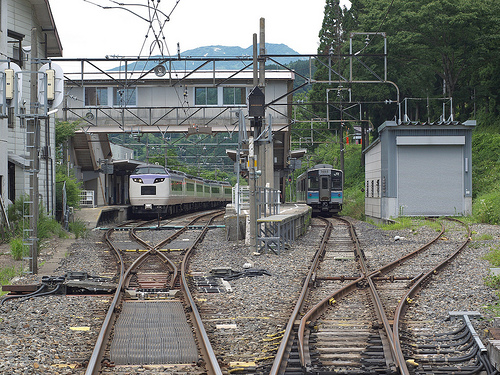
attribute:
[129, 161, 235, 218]
train — facing forward, tan, purple, white, blue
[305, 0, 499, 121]
trees — large, clumped, green, thick, tall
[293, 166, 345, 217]
train — blue, gray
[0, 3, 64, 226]
building — two-story, tan, woode sided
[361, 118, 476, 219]
shed — for storage, gray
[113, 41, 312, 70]
mountain — tall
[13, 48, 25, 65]
window — small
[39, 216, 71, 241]
grass — tall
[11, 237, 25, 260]
grass — tall